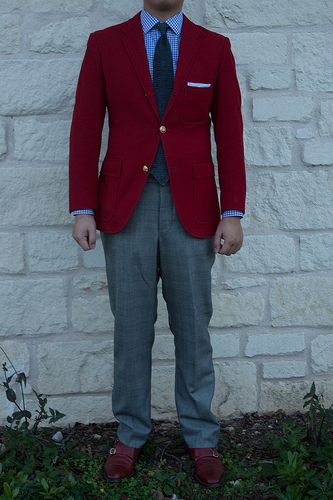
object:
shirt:
[138, 8, 182, 194]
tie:
[149, 19, 172, 187]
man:
[68, 0, 247, 489]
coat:
[68, 11, 246, 238]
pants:
[101, 174, 220, 450]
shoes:
[187, 441, 227, 487]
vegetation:
[0, 346, 333, 497]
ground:
[3, 408, 331, 499]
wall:
[0, 3, 331, 428]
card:
[186, 81, 214, 88]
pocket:
[186, 85, 213, 111]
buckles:
[109, 447, 116, 457]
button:
[157, 125, 168, 133]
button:
[141, 163, 150, 173]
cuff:
[68, 209, 97, 219]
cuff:
[219, 210, 244, 220]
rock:
[50, 431, 65, 446]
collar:
[138, 8, 184, 37]